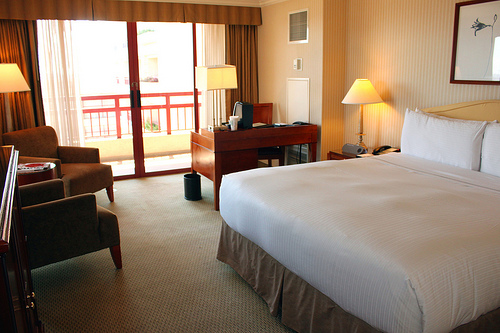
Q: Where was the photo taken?
A: Bedroom.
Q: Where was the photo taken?
A: In a hotel room.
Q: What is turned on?
A: Lamps.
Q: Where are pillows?
A: On the bed.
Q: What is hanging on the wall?
A: A framed painting.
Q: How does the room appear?
A: Clean and tidy.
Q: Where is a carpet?
A: On the floor.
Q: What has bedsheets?
A: A bed.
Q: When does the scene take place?
A: During the daytime.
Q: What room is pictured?
A: A bedroom.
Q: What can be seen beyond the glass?
A: A balcony.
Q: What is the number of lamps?
A: Three.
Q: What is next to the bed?
A: A wood desk.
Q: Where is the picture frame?
A: Mounted to the wall.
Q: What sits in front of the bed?
A: Two chairs.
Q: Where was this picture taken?
A: A bedroom.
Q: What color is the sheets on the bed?
A: The sheets are white.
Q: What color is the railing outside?
A: Its color is red.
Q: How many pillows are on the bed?
A: Two.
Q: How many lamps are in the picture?
A: Three lamps.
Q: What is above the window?
A: A curtain.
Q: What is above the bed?
A: A picture of a flower.